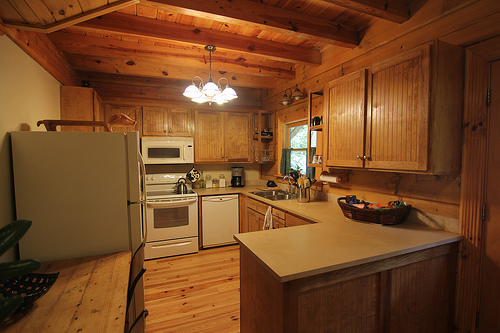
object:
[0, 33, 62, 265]
wall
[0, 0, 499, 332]
building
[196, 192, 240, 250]
dishwasher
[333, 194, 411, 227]
basket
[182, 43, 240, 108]
chandelier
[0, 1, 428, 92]
ceiling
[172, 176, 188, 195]
tea kettle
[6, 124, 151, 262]
refrigerator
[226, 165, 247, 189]
processor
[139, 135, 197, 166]
microwave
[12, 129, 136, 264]
side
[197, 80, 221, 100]
light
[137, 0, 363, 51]
wood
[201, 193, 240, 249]
door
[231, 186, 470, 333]
counter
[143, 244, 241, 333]
floor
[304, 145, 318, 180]
curtain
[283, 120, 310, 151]
window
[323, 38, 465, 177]
cabinets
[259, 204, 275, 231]
towel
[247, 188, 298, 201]
sink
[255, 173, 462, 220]
panels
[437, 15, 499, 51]
panels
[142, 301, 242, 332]
panels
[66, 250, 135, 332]
panels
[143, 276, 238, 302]
panels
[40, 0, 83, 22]
panels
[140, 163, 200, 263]
stove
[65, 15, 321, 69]
beam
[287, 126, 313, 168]
greenery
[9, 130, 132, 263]
sideview